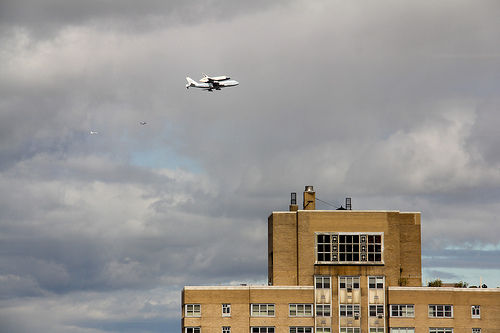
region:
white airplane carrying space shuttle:
[168, 62, 241, 98]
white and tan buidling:
[141, 186, 498, 324]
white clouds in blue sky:
[36, 32, 83, 76]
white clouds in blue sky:
[6, 100, 91, 165]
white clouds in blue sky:
[90, 135, 183, 203]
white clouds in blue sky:
[22, 176, 69, 204]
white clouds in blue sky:
[114, 179, 164, 217]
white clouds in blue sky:
[15, 206, 94, 258]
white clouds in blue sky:
[292, 14, 338, 77]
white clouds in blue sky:
[365, 68, 441, 142]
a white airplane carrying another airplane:
[180, 69, 246, 97]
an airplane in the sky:
[136, 118, 151, 130]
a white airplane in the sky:
[86, 125, 101, 140]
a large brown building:
[170, 186, 499, 331]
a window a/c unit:
[345, 279, 352, 293]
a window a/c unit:
[356, 310, 360, 320]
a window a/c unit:
[379, 312, 384, 321]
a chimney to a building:
[299, 183, 322, 214]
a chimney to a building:
[288, 190, 299, 209]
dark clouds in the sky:
[13, 166, 165, 320]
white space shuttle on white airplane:
[177, 55, 249, 110]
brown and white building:
[176, 176, 497, 321]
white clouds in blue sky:
[27, 18, 102, 119]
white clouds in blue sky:
[51, 135, 96, 199]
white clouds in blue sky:
[57, 218, 115, 263]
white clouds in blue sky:
[121, 245, 169, 282]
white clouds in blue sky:
[210, 105, 251, 132]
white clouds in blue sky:
[326, 72, 367, 107]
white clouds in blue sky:
[371, 32, 436, 110]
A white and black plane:
[177, 70, 257, 92]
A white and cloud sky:
[11, 292, 104, 327]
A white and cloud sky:
[7, 193, 142, 250]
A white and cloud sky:
[146, 183, 264, 275]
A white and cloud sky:
[385, 117, 498, 204]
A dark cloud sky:
[250, 71, 364, 159]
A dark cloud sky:
[380, 61, 486, 155]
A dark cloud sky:
[7, 58, 127, 114]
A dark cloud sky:
[87, 0, 233, 44]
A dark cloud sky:
[0, 1, 74, 49]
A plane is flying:
[183, 73, 241, 92]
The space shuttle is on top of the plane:
[183, 73, 238, 92]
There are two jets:
[86, 117, 149, 137]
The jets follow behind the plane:
[85, 72, 240, 138]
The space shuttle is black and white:
[200, 73, 232, 82]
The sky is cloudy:
[26, 12, 480, 189]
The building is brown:
[178, 192, 498, 332]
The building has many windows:
[178, 229, 483, 331]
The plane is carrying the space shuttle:
[183, 73, 238, 90]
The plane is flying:
[185, 67, 239, 95]